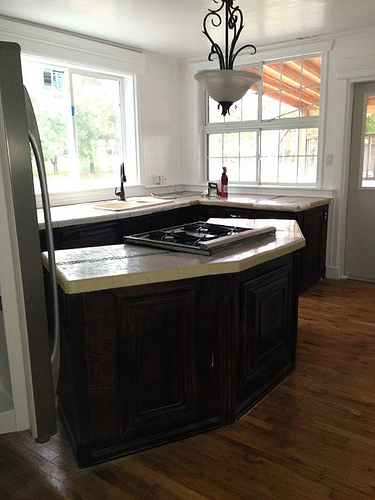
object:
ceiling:
[0, 0, 375, 55]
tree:
[35, 107, 70, 175]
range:
[145, 222, 248, 246]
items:
[207, 166, 228, 198]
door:
[338, 75, 375, 283]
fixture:
[193, 0, 262, 117]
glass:
[193, 68, 262, 102]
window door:
[342, 78, 375, 283]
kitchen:
[0, 0, 374, 500]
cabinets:
[235, 263, 298, 422]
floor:
[0, 277, 375, 497]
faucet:
[115, 162, 127, 201]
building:
[0, 0, 375, 500]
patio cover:
[238, 49, 325, 117]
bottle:
[220, 167, 228, 197]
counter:
[37, 193, 153, 230]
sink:
[93, 199, 174, 212]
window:
[20, 50, 141, 210]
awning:
[239, 51, 325, 125]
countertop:
[37, 191, 330, 230]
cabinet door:
[115, 285, 198, 439]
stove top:
[123, 221, 277, 256]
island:
[40, 217, 307, 470]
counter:
[160, 193, 332, 213]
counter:
[41, 218, 306, 295]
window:
[205, 49, 324, 185]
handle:
[21, 79, 62, 395]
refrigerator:
[0, 39, 61, 443]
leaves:
[80, 116, 92, 135]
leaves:
[50, 113, 62, 127]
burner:
[158, 229, 178, 240]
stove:
[139, 216, 268, 286]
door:
[117, 289, 200, 440]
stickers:
[42, 68, 64, 92]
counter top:
[41, 218, 306, 295]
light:
[248, 6, 323, 38]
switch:
[325, 154, 333, 167]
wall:
[154, 53, 180, 179]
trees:
[75, 104, 120, 173]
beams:
[260, 52, 323, 118]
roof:
[244, 60, 321, 108]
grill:
[123, 221, 277, 256]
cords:
[146, 176, 184, 199]